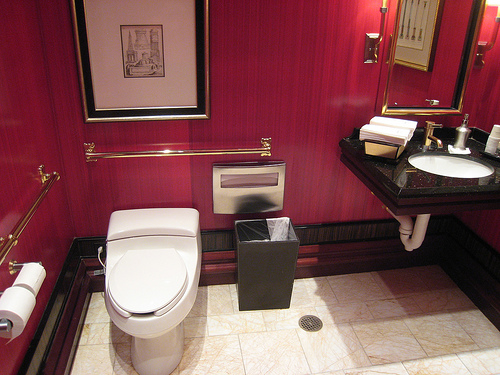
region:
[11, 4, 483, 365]
an elegant bathroom with red walls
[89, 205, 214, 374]
a fancy white toilet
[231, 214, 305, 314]
a bathroom trash can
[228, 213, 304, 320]
a bathroom waste basket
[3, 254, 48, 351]
two rolls of toilet paper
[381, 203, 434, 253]
a pipe under a bathroom sink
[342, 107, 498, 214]
a marble topped sink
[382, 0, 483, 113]
a bathroom mirror with gold trim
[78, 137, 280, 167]
a golden bar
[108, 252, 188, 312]
the lid on a toilet seat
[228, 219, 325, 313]
A garbage can next to the toilet.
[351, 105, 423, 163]
White napkins on the sink.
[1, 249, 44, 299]
Toilet paper on the roll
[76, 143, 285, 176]
Gold railing behind the toilet.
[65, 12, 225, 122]
A picture on the bathroom wall.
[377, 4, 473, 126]
A golden mirror above the sink.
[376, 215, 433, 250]
White pipes under the sink.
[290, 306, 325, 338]
Drainer on the floor.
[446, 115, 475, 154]
Soap dispenser on the sink.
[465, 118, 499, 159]
Small white cups by the sink.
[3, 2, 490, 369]
a beautifully decorated bathroom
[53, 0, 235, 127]
a very nice picture on the wall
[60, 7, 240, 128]
the picture is framed in gold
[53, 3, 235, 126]
the picture is matted in black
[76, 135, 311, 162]
the rails are gold tone as well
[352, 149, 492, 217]
the counter appears to be black marble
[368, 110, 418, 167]
a basket of paper towels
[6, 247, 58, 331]
toilet paper rolls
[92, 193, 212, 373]
the commode is white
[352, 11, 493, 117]
the mirror is framed in gold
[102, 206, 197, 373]
A white bathroom toilet.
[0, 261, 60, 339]
Two rolls of toilet paper.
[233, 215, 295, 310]
A dark brown garbage pail.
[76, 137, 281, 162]
A metal rail attached to the wall.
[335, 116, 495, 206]
A black counter top.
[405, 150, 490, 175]
A round white sink.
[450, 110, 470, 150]
A silver soap dispenser.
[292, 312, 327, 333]
A drain on the bathroom floor.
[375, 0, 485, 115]
A mirror on the wall above the sink.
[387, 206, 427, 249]
The sink has a white drainage pipe.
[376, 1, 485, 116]
Mirror on the wall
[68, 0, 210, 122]
Picture hanging on the wall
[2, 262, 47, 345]
Two rolls of toilet paper on the rollers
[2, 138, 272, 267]
Gold racks on the wall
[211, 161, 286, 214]
Toilet seat cover holder on the wall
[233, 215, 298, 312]
Garbage can on the floor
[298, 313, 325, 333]
Drain on the floor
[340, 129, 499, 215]
Black marble bathroom counter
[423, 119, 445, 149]
Faucet over the sink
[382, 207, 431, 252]
Pipe under the sink